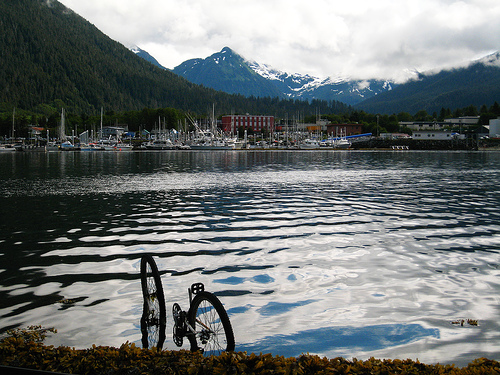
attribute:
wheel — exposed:
[138, 250, 167, 320]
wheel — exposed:
[186, 290, 235, 353]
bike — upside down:
[136, 251, 239, 356]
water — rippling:
[0, 144, 498, 370]